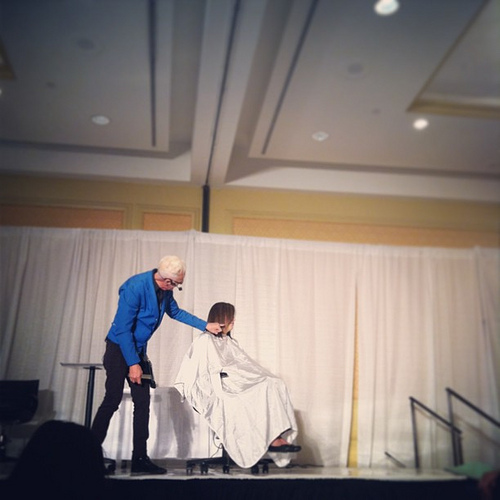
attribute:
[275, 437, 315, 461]
shoe — black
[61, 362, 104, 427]
table — small, waist high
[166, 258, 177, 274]
hair — trimmed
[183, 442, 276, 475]
chair — swivel 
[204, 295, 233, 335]
hair — improved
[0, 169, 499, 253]
trim — golden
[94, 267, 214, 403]
sweater — vibrant, blue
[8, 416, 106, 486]
head — spectators 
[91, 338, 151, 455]
slacks — black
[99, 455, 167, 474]
shoes — black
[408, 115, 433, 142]
light — on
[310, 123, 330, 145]
light — on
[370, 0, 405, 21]
light — on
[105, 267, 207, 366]
sweater — blue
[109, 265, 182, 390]
cardigan — blue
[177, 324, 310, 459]
cape — white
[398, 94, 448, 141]
lighting — overhead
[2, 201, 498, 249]
wall — orange